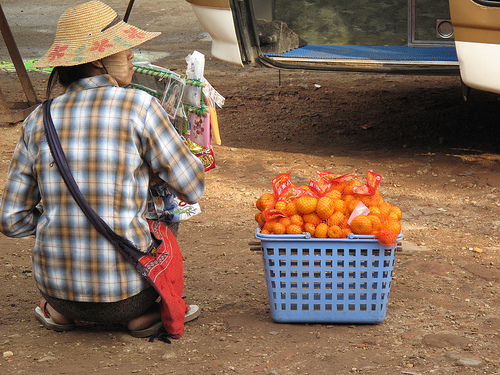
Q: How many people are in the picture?
A: One.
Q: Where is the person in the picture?
A: Beside the blue basket.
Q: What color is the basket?
A: Blue.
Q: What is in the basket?
A: Fruit.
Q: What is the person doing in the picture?
A: Squatting.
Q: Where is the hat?
A: On the person's head.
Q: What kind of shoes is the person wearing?
A: Flip flops.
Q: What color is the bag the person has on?
A: Red.